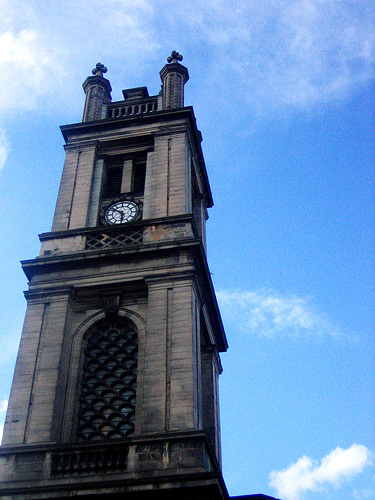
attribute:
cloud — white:
[214, 284, 366, 352]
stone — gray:
[169, 364, 192, 372]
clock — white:
[98, 195, 141, 225]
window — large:
[63, 308, 141, 444]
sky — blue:
[228, 114, 373, 260]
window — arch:
[58, 302, 145, 466]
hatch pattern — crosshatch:
[82, 224, 143, 253]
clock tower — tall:
[72, 55, 218, 282]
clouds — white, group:
[9, 10, 372, 129]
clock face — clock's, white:
[109, 198, 138, 223]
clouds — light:
[11, 29, 135, 51]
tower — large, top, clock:
[0, 50, 228, 497]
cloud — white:
[1, 26, 38, 75]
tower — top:
[16, 49, 245, 496]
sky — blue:
[2, 1, 372, 497]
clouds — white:
[270, 435, 368, 500]